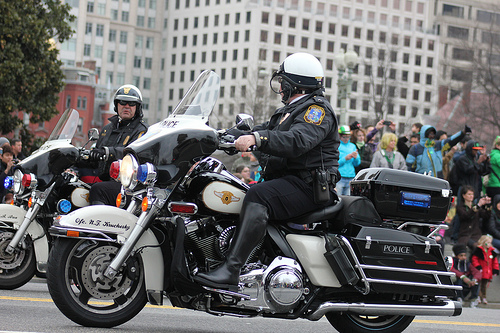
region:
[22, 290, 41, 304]
yellow line on the road.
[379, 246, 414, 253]
lettering on the motorcycle.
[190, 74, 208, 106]
windshield on the motorcycle.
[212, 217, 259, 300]
boot on the officer.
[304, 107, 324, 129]
logo on the officer's jacket.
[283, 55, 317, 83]
helmet on the officer's head.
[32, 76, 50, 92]
leaves on the tree.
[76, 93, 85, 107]
windows on the building.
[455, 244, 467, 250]
hat on person's head.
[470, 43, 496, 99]
limbs on the tree.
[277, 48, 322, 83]
a white helmet on head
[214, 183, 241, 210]
a gold logo on a motorcycle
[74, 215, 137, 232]
black script on the fender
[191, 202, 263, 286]
a tall black leather boot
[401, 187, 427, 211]
a blue light on the motorcycle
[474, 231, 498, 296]
a child in a red and black coat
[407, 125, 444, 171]
a man giving a thumbs up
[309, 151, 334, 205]
a black walkie talkie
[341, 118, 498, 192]
a crowd of people near the street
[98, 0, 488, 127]
a tall building behind the crowd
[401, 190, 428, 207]
Blue light on police motorcycle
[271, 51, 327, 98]
White helmet on policeman's head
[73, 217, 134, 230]
Name of policeman on motorcycle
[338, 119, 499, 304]
Group of people standing in the background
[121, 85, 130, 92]
Logo on policeman's helmet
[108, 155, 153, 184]
Group of lights on front of motorcycle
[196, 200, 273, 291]
Large black boot on policman's leg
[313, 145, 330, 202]
Black walkie talkie on policeman's belt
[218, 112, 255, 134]
Chrome side mirror on motorcycle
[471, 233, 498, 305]
Girl wearing red and black coat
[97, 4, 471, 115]
windows on city building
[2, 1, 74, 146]
green leaves on trees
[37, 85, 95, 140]
red wall of building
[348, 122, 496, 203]
crowd of people standing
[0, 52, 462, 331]
two police on motorbikes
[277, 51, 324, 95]
helmet on cops head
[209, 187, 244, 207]
emblem on bike tank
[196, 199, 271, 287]
black boot on leg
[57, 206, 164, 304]
white fender on bike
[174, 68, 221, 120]
windshield on front of bike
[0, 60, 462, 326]
the men are riding motorcycles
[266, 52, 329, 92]
the helmet is black and white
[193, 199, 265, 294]
the boot is black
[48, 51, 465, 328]
the man is riding a motorcycle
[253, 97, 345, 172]
the jacket is black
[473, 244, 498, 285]
the jacket is black and red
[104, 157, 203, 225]
the lights are blue red and orange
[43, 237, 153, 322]
the tire is black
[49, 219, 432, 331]
the motorcycle has two tires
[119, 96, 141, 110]
the man has sunglasses